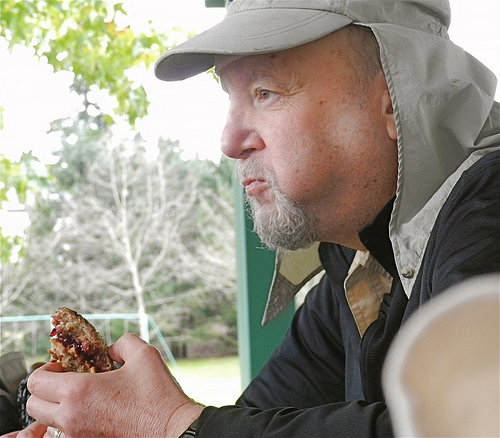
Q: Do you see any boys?
A: No, there are no boys.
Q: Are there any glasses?
A: No, there are no glasses.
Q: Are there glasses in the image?
A: No, there are no glasses.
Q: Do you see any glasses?
A: No, there are no glasses.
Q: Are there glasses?
A: No, there are no glasses.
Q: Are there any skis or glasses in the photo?
A: No, there are no glasses or skis.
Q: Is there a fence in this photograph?
A: Yes, there is a fence.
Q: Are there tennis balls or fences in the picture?
A: Yes, there is a fence.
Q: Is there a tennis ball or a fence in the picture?
A: Yes, there is a fence.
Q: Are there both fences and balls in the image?
A: No, there is a fence but no balls.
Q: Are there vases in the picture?
A: No, there are no vases.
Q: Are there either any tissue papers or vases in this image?
A: No, there are no vases or tissue papers.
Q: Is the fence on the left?
A: Yes, the fence is on the left of the image.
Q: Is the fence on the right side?
A: No, the fence is on the left of the image.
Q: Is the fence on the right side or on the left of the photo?
A: The fence is on the left of the image.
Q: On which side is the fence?
A: The fence is on the left of the image.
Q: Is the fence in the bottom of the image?
A: Yes, the fence is in the bottom of the image.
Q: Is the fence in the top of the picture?
A: No, the fence is in the bottom of the image.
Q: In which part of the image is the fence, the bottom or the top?
A: The fence is in the bottom of the image.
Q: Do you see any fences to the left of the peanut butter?
A: Yes, there is a fence to the left of the peanut butter.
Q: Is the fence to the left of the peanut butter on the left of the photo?
A: Yes, the fence is to the left of the peanut butter.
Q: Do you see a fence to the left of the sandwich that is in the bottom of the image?
A: Yes, there is a fence to the left of the sandwich.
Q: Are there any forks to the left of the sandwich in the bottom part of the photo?
A: No, there is a fence to the left of the sandwich.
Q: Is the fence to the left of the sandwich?
A: Yes, the fence is to the left of the sandwich.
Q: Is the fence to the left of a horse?
A: No, the fence is to the left of the sandwich.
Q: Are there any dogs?
A: No, there are no dogs.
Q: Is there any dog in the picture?
A: No, there are no dogs.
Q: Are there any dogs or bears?
A: No, there are no dogs or bears.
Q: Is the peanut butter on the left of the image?
A: Yes, the peanut butter is on the left of the image.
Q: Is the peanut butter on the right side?
A: No, the peanut butter is on the left of the image.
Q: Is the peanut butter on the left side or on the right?
A: The peanut butter is on the left of the image.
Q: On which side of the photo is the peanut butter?
A: The peanut butter is on the left of the image.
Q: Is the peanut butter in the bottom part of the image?
A: Yes, the peanut butter is in the bottom of the image.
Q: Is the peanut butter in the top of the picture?
A: No, the peanut butter is in the bottom of the image.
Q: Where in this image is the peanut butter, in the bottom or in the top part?
A: The peanut butter is in the bottom of the image.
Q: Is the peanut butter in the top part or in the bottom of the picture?
A: The peanut butter is in the bottom of the image.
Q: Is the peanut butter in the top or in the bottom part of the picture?
A: The peanut butter is in the bottom of the image.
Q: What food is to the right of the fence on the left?
A: The food is peanut butter.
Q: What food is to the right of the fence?
A: The food is peanut butter.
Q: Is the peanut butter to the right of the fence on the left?
A: Yes, the peanut butter is to the right of the fence.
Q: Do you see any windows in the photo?
A: Yes, there is a window.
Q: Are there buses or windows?
A: Yes, there is a window.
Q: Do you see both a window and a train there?
A: No, there is a window but no trains.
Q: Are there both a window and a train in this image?
A: No, there is a window but no trains.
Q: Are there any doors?
A: No, there are no doors.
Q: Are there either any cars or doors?
A: No, there are no doors or cars.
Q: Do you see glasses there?
A: No, there are no glasses.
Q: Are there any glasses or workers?
A: No, there are no glasses or workers.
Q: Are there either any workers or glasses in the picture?
A: No, there are no glasses or workers.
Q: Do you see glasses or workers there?
A: No, there are no glasses or workers.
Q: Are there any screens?
A: No, there are no screens.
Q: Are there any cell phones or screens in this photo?
A: No, there are no screens or cell phones.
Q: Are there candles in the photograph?
A: No, there are no candles.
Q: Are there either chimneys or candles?
A: No, there are no candles or chimneys.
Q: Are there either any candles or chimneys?
A: No, there are no candles or chimneys.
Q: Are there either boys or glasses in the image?
A: No, there are no glasses or boys.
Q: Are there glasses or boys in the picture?
A: No, there are no glasses or boys.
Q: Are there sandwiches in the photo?
A: Yes, there is a sandwich.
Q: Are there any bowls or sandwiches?
A: Yes, there is a sandwich.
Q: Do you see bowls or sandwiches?
A: Yes, there is a sandwich.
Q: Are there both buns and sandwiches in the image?
A: No, there is a sandwich but no buns.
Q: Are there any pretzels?
A: No, there are no pretzels.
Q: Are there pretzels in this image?
A: No, there are no pretzels.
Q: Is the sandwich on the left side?
A: Yes, the sandwich is on the left of the image.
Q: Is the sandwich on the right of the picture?
A: No, the sandwich is on the left of the image.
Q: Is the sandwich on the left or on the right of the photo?
A: The sandwich is on the left of the image.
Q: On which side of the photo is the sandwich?
A: The sandwich is on the left of the image.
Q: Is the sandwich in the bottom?
A: Yes, the sandwich is in the bottom of the image.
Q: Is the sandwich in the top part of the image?
A: No, the sandwich is in the bottom of the image.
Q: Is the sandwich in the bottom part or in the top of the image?
A: The sandwich is in the bottom of the image.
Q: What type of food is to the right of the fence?
A: The food is a sandwich.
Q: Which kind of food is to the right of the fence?
A: The food is a sandwich.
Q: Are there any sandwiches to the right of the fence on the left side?
A: Yes, there is a sandwich to the right of the fence.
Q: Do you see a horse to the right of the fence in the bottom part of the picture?
A: No, there is a sandwich to the right of the fence.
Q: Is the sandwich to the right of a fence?
A: Yes, the sandwich is to the right of a fence.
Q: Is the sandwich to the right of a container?
A: No, the sandwich is to the right of a fence.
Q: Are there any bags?
A: No, there are no bags.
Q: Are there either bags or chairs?
A: No, there are no bags or chairs.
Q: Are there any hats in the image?
A: Yes, there is a hat.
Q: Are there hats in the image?
A: Yes, there is a hat.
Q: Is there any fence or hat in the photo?
A: Yes, there is a hat.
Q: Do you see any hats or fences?
A: Yes, there is a hat.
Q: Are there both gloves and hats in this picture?
A: No, there is a hat but no gloves.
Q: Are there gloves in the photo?
A: No, there are no gloves.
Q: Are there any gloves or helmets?
A: No, there are no gloves or helmets.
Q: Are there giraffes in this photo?
A: No, there are no giraffes.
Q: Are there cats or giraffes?
A: No, there are no giraffes or cats.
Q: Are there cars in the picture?
A: No, there are no cars.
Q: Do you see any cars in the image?
A: No, there are no cars.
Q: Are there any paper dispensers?
A: No, there are no paper dispensers.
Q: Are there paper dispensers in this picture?
A: No, there are no paper dispensers.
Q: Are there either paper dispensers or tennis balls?
A: No, there are no paper dispensers or tennis balls.